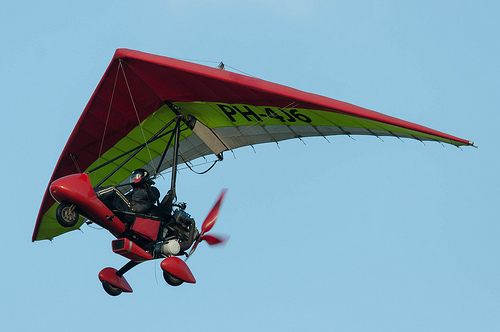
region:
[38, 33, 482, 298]
a person is hang gliding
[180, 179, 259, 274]
the propeller is in motion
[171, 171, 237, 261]
the propeller is red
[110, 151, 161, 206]
the pilot is wearing a helmet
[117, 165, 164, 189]
the helmet is black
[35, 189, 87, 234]
the wheel is black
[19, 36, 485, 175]
the kite is red, green, and grey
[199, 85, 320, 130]
letters and numbers under the kite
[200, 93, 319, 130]
the writing is black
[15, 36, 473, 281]
the kite is attached to a car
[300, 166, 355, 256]
sky behind the aircraft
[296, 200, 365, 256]
sky with no clouds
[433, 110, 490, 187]
tip of the wing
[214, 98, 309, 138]
red numbers and letters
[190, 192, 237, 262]
propellor on the plane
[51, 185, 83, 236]
tire on the object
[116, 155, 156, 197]
helmet on the person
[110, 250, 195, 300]
two wheels on the object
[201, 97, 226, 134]
yellow part of the object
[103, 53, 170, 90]
red part of the plane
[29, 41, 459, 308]
A glider attached to a motorcycle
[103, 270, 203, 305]
Two small black wheels on the vehicle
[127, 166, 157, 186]
A black helmet on the pilot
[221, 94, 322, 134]
The sail says "PH-4J6"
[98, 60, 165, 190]
Strings holding the vehicle up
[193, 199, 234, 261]
A red propeller on the back of the vehicle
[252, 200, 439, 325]
An open blue sky behind the vehicle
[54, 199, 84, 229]
The front landing gear of the aircraft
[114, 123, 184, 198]
Thin black metal poles on the vehicle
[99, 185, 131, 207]
Yellow stripes on the man's pants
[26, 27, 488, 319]
Man flying ultralight aircraft.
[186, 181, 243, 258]
Propeller of ultralight aircraft.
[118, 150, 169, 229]
Pilot of ultralight aircraft.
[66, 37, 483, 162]
Wing of ultralight aircraft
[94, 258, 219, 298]
Landing gear of ultralight aircraft.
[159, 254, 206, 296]
Right landing gear wheel.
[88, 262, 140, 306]
Left landing gear wheel.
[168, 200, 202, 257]
Engine of ultralight aircraft.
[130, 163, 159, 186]
Pilot's helmet.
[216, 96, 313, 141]
Numbers and letters on wing.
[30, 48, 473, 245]
red green and white hang glider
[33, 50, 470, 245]
hang glider in air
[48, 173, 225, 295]
small plane with glider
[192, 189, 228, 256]
propeller on plane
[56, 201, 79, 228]
black tire on plane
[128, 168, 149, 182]
black plastic helmet on head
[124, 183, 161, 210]
black padded jacket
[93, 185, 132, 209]
black and white pants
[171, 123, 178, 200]
black metal support pole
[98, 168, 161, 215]
man flying on hang glider plane